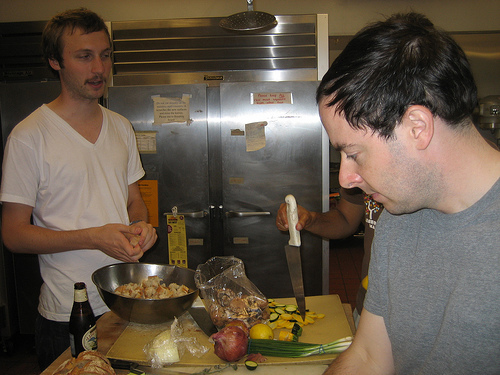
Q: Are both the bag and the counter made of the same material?
A: No, the bag is made of plastic and the counter is made of metal.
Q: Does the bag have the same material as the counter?
A: No, the bag is made of plastic and the counter is made of metal.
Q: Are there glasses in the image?
A: No, there are no glasses.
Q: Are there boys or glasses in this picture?
A: No, there are no glasses or boys.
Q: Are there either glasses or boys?
A: No, there are no glasses or boys.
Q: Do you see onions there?
A: Yes, there are onions.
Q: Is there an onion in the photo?
A: Yes, there are onions.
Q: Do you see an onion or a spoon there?
A: Yes, there are onions.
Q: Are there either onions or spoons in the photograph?
A: Yes, there are onions.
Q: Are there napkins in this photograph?
A: No, there are no napkins.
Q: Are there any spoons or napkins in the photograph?
A: No, there are no napkins or spoons.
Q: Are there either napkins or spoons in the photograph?
A: No, there are no napkins or spoons.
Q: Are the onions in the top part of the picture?
A: No, the onions are in the bottom of the image.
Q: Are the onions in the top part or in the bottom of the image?
A: The onions are in the bottom of the image.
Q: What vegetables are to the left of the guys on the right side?
A: The vegetables are onions.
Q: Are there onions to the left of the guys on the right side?
A: Yes, there are onions to the left of the guys.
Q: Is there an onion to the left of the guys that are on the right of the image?
A: Yes, there are onions to the left of the guys.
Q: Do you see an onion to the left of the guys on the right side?
A: Yes, there are onions to the left of the guys.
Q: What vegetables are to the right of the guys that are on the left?
A: The vegetables are onions.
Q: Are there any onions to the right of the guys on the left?
A: Yes, there are onions to the right of the guys.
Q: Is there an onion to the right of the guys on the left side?
A: Yes, there are onions to the right of the guys.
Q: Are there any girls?
A: No, there are no girls.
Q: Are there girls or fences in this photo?
A: No, there are no girls or fences.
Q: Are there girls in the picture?
A: No, there are no girls.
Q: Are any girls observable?
A: No, there are no girls.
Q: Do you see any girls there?
A: No, there are no girls.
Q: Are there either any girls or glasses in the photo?
A: No, there are no girls or glasses.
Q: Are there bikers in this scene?
A: No, there are no bikers.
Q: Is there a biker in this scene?
A: No, there are no bikers.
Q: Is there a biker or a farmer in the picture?
A: No, there are no bikers or farmers.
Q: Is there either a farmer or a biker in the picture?
A: No, there are no bikers or farmers.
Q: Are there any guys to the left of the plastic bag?
A: Yes, there are guys to the left of the bag.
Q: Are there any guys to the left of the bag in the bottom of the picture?
A: Yes, there are guys to the left of the bag.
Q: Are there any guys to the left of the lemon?
A: Yes, there are guys to the left of the lemon.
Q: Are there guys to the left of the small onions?
A: Yes, there are guys to the left of the onions.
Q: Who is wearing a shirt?
A: The guys are wearing a shirt.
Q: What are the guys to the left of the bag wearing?
A: The guys are wearing a shirt.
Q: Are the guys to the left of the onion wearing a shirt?
A: Yes, the guys are wearing a shirt.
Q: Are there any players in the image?
A: No, there are no players.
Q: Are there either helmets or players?
A: No, there are no players or helmets.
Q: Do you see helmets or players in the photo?
A: No, there are no players or helmets.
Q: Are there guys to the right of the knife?
A: Yes, there are guys to the right of the knife.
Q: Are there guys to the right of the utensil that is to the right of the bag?
A: Yes, there are guys to the right of the knife.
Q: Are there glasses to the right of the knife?
A: No, there are guys to the right of the knife.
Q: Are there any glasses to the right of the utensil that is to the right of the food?
A: No, there are guys to the right of the knife.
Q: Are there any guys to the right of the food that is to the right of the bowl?
A: Yes, there are guys to the right of the food.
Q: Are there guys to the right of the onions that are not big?
A: Yes, there are guys to the right of the onions.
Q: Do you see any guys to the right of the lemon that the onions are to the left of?
A: Yes, there are guys to the right of the lemon.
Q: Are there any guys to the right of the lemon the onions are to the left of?
A: Yes, there are guys to the right of the lemon.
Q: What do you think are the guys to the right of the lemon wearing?
A: The guys are wearing a shirt.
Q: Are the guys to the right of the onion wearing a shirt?
A: Yes, the guys are wearing a shirt.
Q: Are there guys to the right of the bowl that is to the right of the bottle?
A: Yes, there are guys to the right of the bowl.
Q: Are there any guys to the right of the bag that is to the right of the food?
A: Yes, there are guys to the right of the bag.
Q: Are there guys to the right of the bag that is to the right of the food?
A: Yes, there are guys to the right of the bag.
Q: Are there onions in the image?
A: Yes, there is an onion.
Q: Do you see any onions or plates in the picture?
A: Yes, there is an onion.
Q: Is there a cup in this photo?
A: No, there are no cups.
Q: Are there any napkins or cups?
A: No, there are no cups or napkins.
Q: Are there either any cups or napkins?
A: No, there are no cups or napkins.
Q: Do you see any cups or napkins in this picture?
A: No, there are no cups or napkins.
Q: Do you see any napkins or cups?
A: No, there are no cups or napkins.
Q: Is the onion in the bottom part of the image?
A: Yes, the onion is in the bottom of the image.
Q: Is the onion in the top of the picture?
A: No, the onion is in the bottom of the image.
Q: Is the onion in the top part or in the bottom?
A: The onion is in the bottom of the image.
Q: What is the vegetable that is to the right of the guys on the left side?
A: The vegetable is an onion.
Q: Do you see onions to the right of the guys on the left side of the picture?
A: Yes, there is an onion to the right of the guys.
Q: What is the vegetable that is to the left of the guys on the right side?
A: The vegetable is an onion.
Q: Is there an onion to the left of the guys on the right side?
A: Yes, there is an onion to the left of the guys.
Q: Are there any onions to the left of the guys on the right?
A: Yes, there is an onion to the left of the guys.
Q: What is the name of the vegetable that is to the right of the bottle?
A: The vegetable is an onion.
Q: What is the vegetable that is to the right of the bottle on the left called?
A: The vegetable is an onion.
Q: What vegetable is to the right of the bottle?
A: The vegetable is an onion.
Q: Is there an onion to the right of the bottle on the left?
A: Yes, there is an onion to the right of the bottle.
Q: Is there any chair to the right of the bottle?
A: No, there is an onion to the right of the bottle.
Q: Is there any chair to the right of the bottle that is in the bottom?
A: No, there is an onion to the right of the bottle.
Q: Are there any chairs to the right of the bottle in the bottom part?
A: No, there is an onion to the right of the bottle.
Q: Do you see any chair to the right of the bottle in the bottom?
A: No, there is an onion to the right of the bottle.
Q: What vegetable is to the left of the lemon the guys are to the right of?
A: The vegetable is an onion.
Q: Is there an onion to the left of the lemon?
A: Yes, there is an onion to the left of the lemon.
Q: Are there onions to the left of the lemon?
A: Yes, there is an onion to the left of the lemon.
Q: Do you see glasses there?
A: No, there are no glasses.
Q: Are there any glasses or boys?
A: No, there are no glasses or boys.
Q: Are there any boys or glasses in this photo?
A: No, there are no glasses or boys.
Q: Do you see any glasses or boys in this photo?
A: No, there are no glasses or boys.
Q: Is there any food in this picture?
A: Yes, there is food.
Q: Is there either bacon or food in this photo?
A: Yes, there is food.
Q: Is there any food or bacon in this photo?
A: Yes, there is food.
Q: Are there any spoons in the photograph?
A: No, there are no spoons.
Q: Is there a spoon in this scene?
A: No, there are no spoons.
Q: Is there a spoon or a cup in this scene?
A: No, there are no spoons or cups.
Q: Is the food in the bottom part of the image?
A: Yes, the food is in the bottom of the image.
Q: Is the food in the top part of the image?
A: No, the food is in the bottom of the image.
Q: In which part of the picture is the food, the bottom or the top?
A: The food is in the bottom of the image.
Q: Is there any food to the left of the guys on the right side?
A: Yes, there is food to the left of the guys.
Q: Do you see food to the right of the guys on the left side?
A: Yes, there is food to the right of the guys.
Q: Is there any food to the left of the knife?
A: Yes, there is food to the left of the knife.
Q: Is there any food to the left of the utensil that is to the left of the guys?
A: Yes, there is food to the left of the knife.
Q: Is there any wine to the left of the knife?
A: No, there is food to the left of the knife.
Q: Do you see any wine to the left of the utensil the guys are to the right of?
A: No, there is food to the left of the knife.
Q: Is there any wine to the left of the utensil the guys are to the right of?
A: No, there is food to the left of the knife.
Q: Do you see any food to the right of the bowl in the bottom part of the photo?
A: Yes, there is food to the right of the bowl.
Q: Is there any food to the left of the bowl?
A: No, the food is to the right of the bowl.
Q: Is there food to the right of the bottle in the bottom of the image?
A: Yes, there is food to the right of the bottle.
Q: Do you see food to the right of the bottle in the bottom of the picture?
A: Yes, there is food to the right of the bottle.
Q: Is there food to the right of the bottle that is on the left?
A: Yes, there is food to the right of the bottle.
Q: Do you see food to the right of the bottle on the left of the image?
A: Yes, there is food to the right of the bottle.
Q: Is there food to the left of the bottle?
A: No, the food is to the right of the bottle.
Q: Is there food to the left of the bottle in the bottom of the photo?
A: No, the food is to the right of the bottle.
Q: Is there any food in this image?
A: Yes, there is food.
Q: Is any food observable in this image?
A: Yes, there is food.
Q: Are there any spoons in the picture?
A: No, there are no spoons.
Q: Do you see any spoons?
A: No, there are no spoons.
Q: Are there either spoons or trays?
A: No, there are no spoons or trays.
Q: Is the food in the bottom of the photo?
A: Yes, the food is in the bottom of the image.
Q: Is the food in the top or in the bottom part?
A: The food is in the bottom of the image.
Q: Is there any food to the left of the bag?
A: Yes, there is food to the left of the bag.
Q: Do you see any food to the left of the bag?
A: Yes, there is food to the left of the bag.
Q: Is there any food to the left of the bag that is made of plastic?
A: Yes, there is food to the left of the bag.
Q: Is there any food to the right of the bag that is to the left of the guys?
A: No, the food is to the left of the bag.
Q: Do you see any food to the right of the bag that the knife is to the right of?
A: No, the food is to the left of the bag.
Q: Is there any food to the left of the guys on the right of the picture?
A: Yes, there is food to the left of the guys.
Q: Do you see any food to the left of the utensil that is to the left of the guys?
A: Yes, there is food to the left of the knife.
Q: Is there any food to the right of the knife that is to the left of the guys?
A: No, the food is to the left of the knife.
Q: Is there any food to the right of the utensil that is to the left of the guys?
A: No, the food is to the left of the knife.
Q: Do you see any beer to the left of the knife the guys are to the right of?
A: No, there is food to the left of the knife.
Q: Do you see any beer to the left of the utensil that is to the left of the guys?
A: No, there is food to the left of the knife.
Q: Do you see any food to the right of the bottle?
A: Yes, there is food to the right of the bottle.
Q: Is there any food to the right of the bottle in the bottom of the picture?
A: Yes, there is food to the right of the bottle.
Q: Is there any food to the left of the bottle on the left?
A: No, the food is to the right of the bottle.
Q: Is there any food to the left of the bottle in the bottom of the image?
A: No, the food is to the right of the bottle.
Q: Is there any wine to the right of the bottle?
A: No, there is food to the right of the bottle.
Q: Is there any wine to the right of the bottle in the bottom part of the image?
A: No, there is food to the right of the bottle.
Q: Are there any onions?
A: Yes, there are onions.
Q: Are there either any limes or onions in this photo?
A: Yes, there are onions.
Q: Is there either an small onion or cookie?
A: Yes, there are small onions.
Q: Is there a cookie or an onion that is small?
A: Yes, the onions are small.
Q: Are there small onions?
A: Yes, there are small onions.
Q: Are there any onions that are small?
A: Yes, there are onions that are small.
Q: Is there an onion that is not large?
A: Yes, there are small onions.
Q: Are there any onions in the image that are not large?
A: Yes, there are small onions.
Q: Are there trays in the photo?
A: No, there are no trays.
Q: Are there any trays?
A: No, there are no trays.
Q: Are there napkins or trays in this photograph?
A: No, there are no trays or napkins.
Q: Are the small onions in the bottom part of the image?
A: Yes, the onions are in the bottom of the image.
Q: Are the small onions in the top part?
A: No, the onions are in the bottom of the image.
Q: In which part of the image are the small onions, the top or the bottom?
A: The onions are in the bottom of the image.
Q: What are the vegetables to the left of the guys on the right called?
A: The vegetables are onions.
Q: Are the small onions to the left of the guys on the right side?
A: Yes, the onions are to the left of the guys.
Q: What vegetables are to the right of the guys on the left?
A: The vegetables are onions.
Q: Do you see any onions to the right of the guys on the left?
A: Yes, there are onions to the right of the guys.